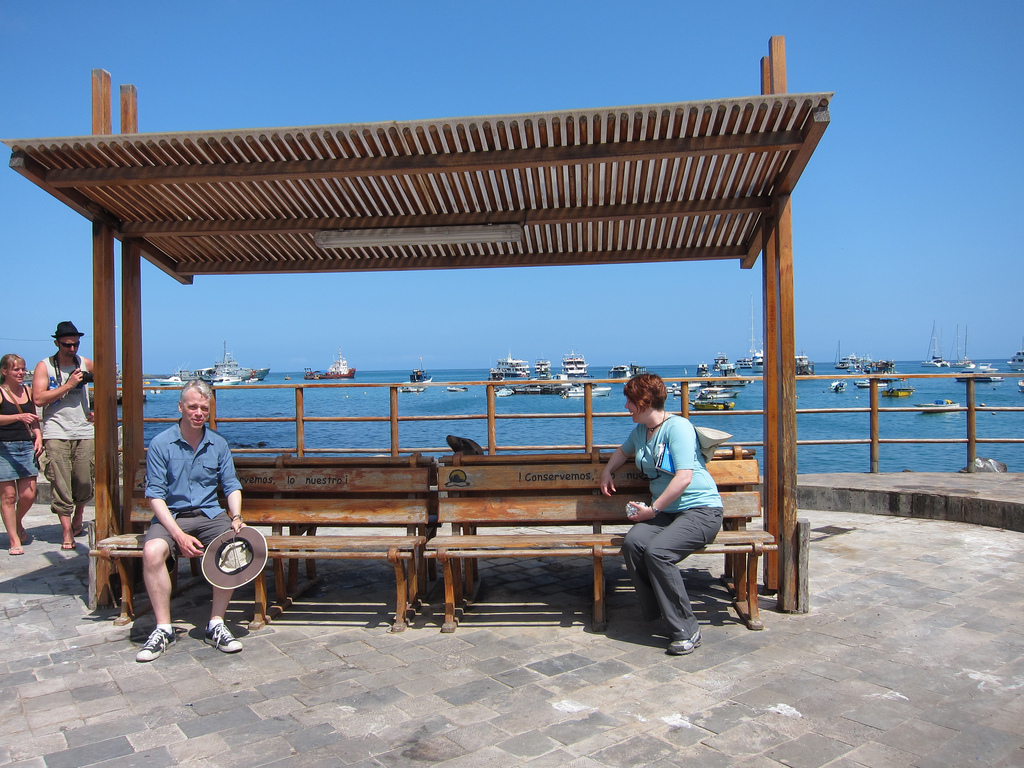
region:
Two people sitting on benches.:
[100, 385, 844, 648]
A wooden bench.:
[106, 449, 427, 608]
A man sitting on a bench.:
[116, 367, 272, 656]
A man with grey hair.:
[132, 377, 292, 672]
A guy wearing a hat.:
[36, 325, 117, 556]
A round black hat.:
[43, 318, 89, 342]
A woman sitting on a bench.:
[564, 367, 762, 663]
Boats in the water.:
[132, 347, 1021, 427]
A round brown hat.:
[189, 524, 282, 595]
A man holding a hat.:
[110, 370, 281, 653]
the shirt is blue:
[660, 437, 700, 464]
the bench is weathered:
[501, 483, 569, 548]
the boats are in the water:
[490, 344, 757, 405]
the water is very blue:
[806, 414, 865, 438]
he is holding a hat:
[212, 512, 270, 602]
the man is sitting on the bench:
[136, 484, 269, 549]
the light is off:
[332, 218, 544, 258]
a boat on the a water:
[903, 388, 955, 443]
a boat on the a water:
[951, 361, 994, 374]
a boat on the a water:
[849, 375, 885, 391]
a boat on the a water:
[826, 347, 874, 374]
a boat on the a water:
[675, 386, 737, 413]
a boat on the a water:
[688, 351, 721, 386]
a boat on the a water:
[510, 367, 568, 393]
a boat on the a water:
[398, 369, 436, 392]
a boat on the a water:
[306, 361, 363, 372]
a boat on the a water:
[201, 356, 258, 386]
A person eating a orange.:
[400, 361, 515, 592]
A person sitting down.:
[130, 375, 271, 661]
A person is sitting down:
[603, 375, 722, 654]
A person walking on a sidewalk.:
[28, 318, 98, 550]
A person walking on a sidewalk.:
[2, 352, 44, 555]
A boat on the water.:
[303, 348, 354, 381]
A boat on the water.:
[186, 339, 272, 385]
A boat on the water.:
[912, 394, 970, 414]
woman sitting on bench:
[595, 365, 736, 672]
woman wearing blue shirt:
[627, 410, 726, 519]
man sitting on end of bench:
[131, 368, 264, 675]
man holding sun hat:
[188, 521, 274, 599]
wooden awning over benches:
[3, 88, 838, 292]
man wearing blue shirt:
[140, 422, 249, 530]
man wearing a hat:
[42, 314, 84, 344]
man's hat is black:
[45, 319, 87, 345]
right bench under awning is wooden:
[415, 451, 783, 626]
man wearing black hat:
[32, 318, 95, 557]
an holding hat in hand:
[128, 376, 271, 668]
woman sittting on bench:
[599, 373, 747, 665]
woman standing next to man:
[0, 352, 47, 556]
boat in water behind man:
[304, 357, 359, 386]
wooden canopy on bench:
[0, 89, 840, 283]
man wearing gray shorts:
[131, 379, 269, 663]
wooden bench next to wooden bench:
[418, 429, 779, 631]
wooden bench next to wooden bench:
[94, 467, 429, 629]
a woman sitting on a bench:
[598, 371, 732, 660]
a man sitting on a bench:
[137, 370, 243, 672]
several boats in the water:
[288, 345, 918, 426]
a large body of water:
[310, 343, 849, 402]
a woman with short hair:
[623, 374, 671, 412]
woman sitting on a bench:
[589, 358, 735, 656]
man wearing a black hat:
[23, 307, 107, 564]